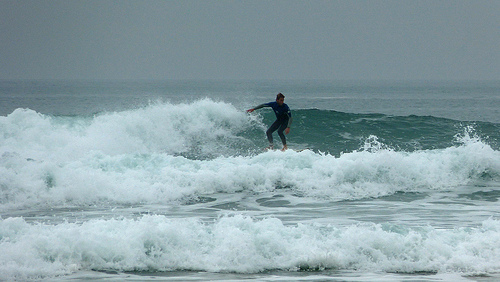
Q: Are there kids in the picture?
A: No, there are no kids.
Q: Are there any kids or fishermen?
A: No, there are no kids or fishermen.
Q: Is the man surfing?
A: Yes, the man is surfing.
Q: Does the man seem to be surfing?
A: Yes, the man is surfing.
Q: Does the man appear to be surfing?
A: Yes, the man is surfing.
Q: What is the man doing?
A: The man is surfing.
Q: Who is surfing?
A: The man is surfing.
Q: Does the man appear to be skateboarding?
A: No, the man is surfing.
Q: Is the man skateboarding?
A: No, the man is surfing.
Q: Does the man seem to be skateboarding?
A: No, the man is surfing.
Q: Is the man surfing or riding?
A: The man is surfing.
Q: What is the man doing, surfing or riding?
A: The man is surfing.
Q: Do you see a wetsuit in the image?
A: Yes, there is a wetsuit.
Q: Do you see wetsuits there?
A: Yes, there is a wetsuit.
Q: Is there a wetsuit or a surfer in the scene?
A: Yes, there is a wetsuit.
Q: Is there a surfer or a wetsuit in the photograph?
A: Yes, there is a wetsuit.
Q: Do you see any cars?
A: No, there are no cars.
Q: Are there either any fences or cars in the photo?
A: No, there are no cars or fences.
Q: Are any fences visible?
A: No, there are no fences.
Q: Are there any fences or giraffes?
A: No, there are no fences or giraffes.